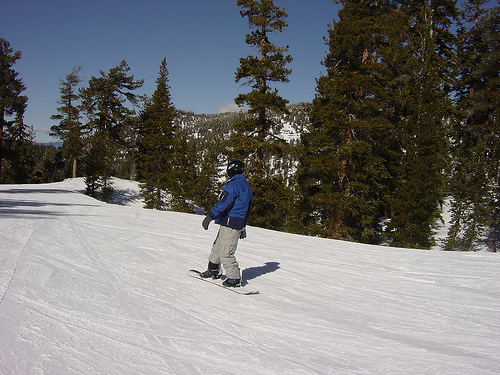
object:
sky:
[33, 8, 179, 50]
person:
[202, 152, 257, 300]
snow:
[24, 220, 175, 364]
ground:
[33, 226, 220, 358]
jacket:
[208, 176, 252, 220]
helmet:
[225, 161, 247, 177]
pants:
[211, 220, 244, 281]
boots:
[204, 264, 246, 285]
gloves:
[203, 211, 212, 230]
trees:
[318, 20, 428, 241]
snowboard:
[184, 262, 254, 303]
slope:
[47, 177, 170, 252]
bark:
[347, 134, 352, 144]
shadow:
[242, 259, 281, 285]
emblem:
[228, 161, 238, 171]